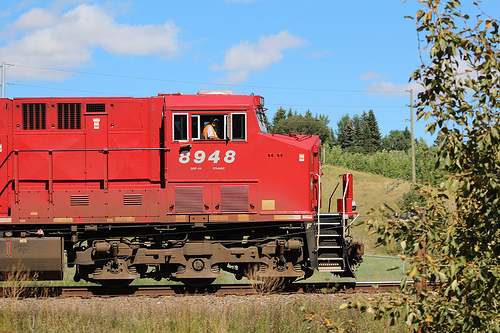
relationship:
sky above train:
[1, 1, 493, 107] [1, 85, 361, 297]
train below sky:
[1, 85, 361, 297] [1, 1, 493, 107]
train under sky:
[1, 85, 361, 297] [1, 1, 493, 107]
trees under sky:
[268, 99, 422, 174] [1, 1, 493, 107]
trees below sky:
[268, 99, 422, 174] [1, 1, 493, 107]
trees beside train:
[268, 99, 422, 174] [1, 85, 361, 297]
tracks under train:
[4, 266, 465, 300] [1, 85, 361, 297]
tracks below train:
[4, 266, 465, 300] [1, 85, 361, 297]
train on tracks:
[1, 85, 361, 297] [4, 266, 465, 300]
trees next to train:
[268, 99, 422, 174] [1, 85, 361, 297]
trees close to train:
[268, 99, 422, 174] [1, 85, 361, 297]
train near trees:
[1, 85, 361, 297] [268, 99, 422, 174]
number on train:
[172, 131, 193, 167] [0, 66, 417, 304]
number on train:
[174, 141, 252, 167] [1, 89, 361, 296]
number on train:
[172, 138, 239, 169] [1, 89, 361, 296]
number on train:
[174, 149, 235, 163] [0, 64, 387, 288]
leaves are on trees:
[273, 104, 411, 142] [268, 99, 422, 174]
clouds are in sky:
[1, 4, 296, 88] [1, 1, 493, 107]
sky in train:
[1, 1, 493, 107] [1, 89, 361, 296]